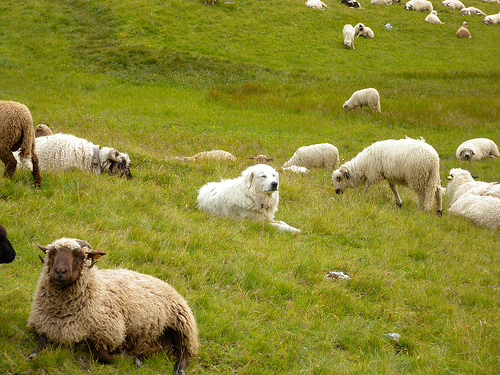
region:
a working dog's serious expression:
[252, 168, 284, 198]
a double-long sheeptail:
[14, 113, 40, 162]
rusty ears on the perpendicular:
[32, 241, 113, 268]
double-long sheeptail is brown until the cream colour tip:
[15, 151, 37, 176]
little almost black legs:
[25, 328, 194, 373]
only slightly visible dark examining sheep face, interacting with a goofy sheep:
[0, 224, 23, 270]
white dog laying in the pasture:
[192, 166, 304, 236]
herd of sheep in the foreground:
[0, 63, 498, 365]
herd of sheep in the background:
[305, 2, 499, 56]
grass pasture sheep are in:
[5, 3, 499, 374]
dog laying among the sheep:
[194, 159, 301, 238]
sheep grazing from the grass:
[325, 141, 448, 211]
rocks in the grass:
[323, 264, 402, 345]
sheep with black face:
[31, 127, 136, 184]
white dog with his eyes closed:
[193, 161, 301, 239]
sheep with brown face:
[23, 233, 205, 373]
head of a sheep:
[42, 235, 102, 293]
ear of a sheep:
[90, 233, 115, 275]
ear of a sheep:
[27, 229, 57, 254]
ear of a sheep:
[336, 152, 348, 179]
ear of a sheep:
[106, 142, 126, 160]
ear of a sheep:
[443, 166, 455, 184]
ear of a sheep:
[473, 169, 480, 183]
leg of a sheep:
[155, 336, 193, 368]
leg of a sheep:
[102, 329, 132, 369]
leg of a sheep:
[26, 132, 43, 189]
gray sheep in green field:
[26, 225, 230, 367]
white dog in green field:
[183, 148, 297, 249]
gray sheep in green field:
[26, 118, 138, 202]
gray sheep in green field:
[256, 131, 334, 172]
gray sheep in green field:
[316, 124, 463, 236]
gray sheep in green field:
[313, 72, 401, 120]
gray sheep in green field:
[329, 12, 384, 54]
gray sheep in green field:
[436, 158, 498, 210]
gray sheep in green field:
[436, 131, 496, 171]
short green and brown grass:
[229, 261, 329, 303]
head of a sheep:
[6, 218, 113, 290]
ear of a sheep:
[93, 235, 117, 263]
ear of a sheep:
[29, 236, 56, 264]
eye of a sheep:
[49, 242, 67, 260]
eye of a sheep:
[65, 249, 92, 267]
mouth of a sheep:
[39, 279, 81, 294]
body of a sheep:
[99, 273, 199, 340]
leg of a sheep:
[135, 342, 232, 373]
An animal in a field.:
[174, 157, 309, 232]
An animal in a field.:
[36, 242, 202, 367]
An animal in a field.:
[321, 144, 446, 214]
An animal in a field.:
[285, 143, 340, 173]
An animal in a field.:
[332, 80, 395, 120]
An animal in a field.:
[339, 20, 351, 45]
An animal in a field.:
[352, 20, 384, 40]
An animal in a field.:
[452, 20, 470, 40]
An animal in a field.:
[433, 167, 495, 228]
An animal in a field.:
[457, 21, 471, 38]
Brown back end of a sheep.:
[0, 99, 42, 186]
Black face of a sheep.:
[1, 224, 16, 264]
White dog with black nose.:
[197, 163, 301, 234]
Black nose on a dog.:
[269, 181, 278, 188]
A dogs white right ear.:
[241, 166, 254, 188]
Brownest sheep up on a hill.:
[455, 21, 472, 38]